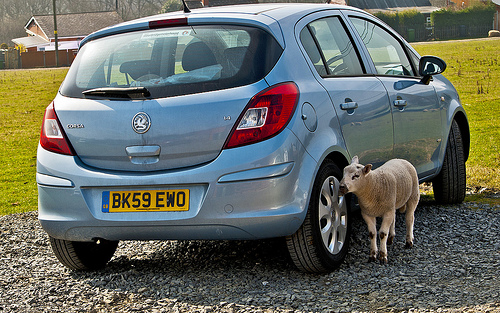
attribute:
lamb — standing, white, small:
[336, 156, 419, 265]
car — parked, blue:
[40, 1, 469, 274]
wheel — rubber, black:
[287, 162, 353, 273]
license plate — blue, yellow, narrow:
[102, 188, 190, 211]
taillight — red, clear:
[224, 81, 301, 156]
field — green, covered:
[0, 35, 499, 216]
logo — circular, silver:
[131, 111, 151, 134]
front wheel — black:
[433, 117, 466, 206]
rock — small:
[262, 279, 270, 287]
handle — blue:
[394, 98, 405, 106]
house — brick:
[13, 10, 125, 50]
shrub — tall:
[370, 4, 496, 43]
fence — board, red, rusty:
[21, 49, 78, 66]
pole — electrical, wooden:
[52, 0, 58, 48]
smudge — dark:
[368, 230, 376, 241]